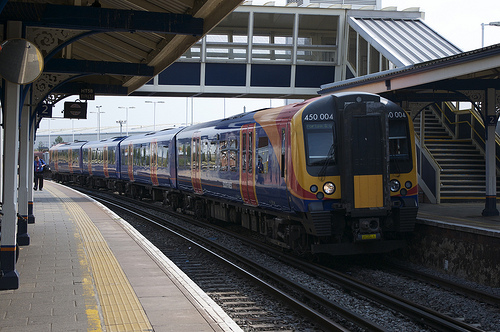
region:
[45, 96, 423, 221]
A long train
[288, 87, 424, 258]
The number 450 004 on train engine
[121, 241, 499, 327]
Train rail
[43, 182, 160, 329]
Yellow line on platform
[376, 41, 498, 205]
Stairs coming down to platform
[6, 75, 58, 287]
Several post on platform building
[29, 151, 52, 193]
A man walking down platform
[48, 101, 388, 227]
Red blue and yellow train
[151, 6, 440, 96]
Catwalk over train rail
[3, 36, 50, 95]
Mirror on train platform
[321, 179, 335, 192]
white light on the front of a train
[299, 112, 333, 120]
white number print on the front of a train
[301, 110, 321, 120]
white text print reading 450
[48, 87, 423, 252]
long red yellow orange and blue train on a track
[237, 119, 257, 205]
red color train door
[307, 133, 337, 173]
train windshield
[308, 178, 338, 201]
three round lights on a train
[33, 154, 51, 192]
man on a train platform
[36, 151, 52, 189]
man in a blue shirt on a train platform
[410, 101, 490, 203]
white and yellow stairs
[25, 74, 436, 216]
A black and blue train.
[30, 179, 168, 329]
a yellow stripe near a loading platform.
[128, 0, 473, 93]
a walkway over a train.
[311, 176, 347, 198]
the right headlight on a train.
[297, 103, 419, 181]
a windshield on the front of a train.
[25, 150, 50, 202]
a person standing near a train.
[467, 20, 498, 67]
a light near a train station.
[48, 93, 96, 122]
a sign hanging from a ceiling.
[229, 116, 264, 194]
doors on the side of a train.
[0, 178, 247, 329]
a loading platform near a train.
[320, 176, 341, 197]
the headlight of a train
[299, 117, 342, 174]
the windshield of a train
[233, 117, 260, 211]
the doors of a train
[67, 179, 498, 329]
metal train tracks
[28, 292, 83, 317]
a brick in the ground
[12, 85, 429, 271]
a train on the tracks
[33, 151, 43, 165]
the head of a man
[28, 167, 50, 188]
a pair of black pants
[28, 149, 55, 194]
a man on the sidewalk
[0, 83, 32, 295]
a pillar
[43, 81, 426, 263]
A train is in the foreground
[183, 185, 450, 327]
Train is on the train tracks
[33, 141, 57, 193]
Person is in the background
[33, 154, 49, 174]
Person is wearing a blue shirt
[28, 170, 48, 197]
Person is wearing black pants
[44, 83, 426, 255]
Train is blue, red and yellow in color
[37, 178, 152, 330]
A long yellow line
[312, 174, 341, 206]
Train light is on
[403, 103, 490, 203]
Stairs are in the background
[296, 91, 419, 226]
End part of the train is black and yellow